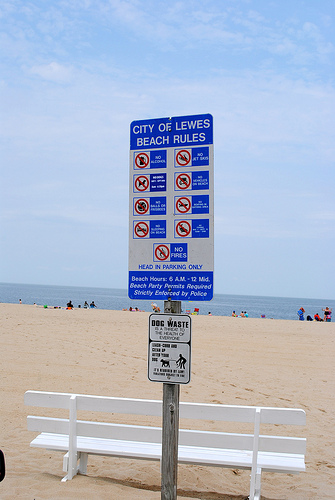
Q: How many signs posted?
A: 2.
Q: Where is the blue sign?
A: Above the black and white sign.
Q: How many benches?
A: 1.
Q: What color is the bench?
A: White.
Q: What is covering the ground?
A: Sand.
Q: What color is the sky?
A: Blue.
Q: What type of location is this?
A: A beach.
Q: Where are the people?
A: At the beach.